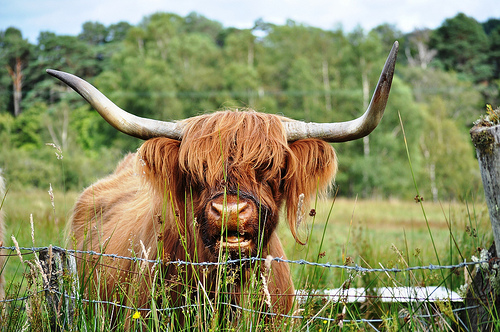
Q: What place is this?
A: It is a field.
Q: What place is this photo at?
A: It is at the field.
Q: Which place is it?
A: It is a field.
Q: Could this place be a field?
A: Yes, it is a field.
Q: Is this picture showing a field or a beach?
A: It is showing a field.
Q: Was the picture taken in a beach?
A: No, the picture was taken in a field.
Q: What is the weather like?
A: It is cloudy.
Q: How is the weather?
A: It is cloudy.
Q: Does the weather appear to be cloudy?
A: Yes, it is cloudy.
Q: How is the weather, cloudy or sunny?
A: It is cloudy.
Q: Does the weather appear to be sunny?
A: No, it is cloudy.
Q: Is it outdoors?
A: Yes, it is outdoors.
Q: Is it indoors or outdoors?
A: It is outdoors.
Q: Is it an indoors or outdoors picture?
A: It is outdoors.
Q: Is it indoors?
A: No, it is outdoors.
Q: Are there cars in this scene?
A: No, there are no cars.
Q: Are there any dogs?
A: No, there are no dogs.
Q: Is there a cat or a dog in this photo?
A: No, there are no dogs or cats.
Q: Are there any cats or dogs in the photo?
A: No, there are no dogs or cats.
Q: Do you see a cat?
A: No, there are no cats.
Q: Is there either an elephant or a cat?
A: No, there are no cats or elephants.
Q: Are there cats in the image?
A: No, there are no cats.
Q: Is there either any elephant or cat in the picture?
A: No, there are no cats or elephants.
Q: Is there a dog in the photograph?
A: No, there are no dogs.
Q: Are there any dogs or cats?
A: No, there are no dogs or cats.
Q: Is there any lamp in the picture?
A: No, there are no lamps.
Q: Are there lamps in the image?
A: No, there are no lamps.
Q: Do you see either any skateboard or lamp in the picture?
A: No, there are no lamps or skateboards.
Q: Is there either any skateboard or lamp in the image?
A: No, there are no lamps or skateboards.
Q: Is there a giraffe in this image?
A: No, there are no giraffes.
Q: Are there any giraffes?
A: No, there are no giraffes.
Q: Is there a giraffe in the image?
A: No, there are no giraffes.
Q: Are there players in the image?
A: No, there are no players.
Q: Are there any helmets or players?
A: No, there are no players or helmets.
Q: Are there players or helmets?
A: No, there are no players or helmets.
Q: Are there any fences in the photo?
A: Yes, there is a fence.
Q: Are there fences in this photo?
A: Yes, there is a fence.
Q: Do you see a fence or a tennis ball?
A: Yes, there is a fence.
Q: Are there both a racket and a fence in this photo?
A: No, there is a fence but no rackets.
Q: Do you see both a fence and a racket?
A: No, there is a fence but no rackets.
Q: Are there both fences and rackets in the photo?
A: No, there is a fence but no rackets.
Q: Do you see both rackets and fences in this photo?
A: No, there is a fence but no rackets.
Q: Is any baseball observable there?
A: No, there are no baseballs.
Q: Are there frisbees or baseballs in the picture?
A: No, there are no baseballs or frisbees.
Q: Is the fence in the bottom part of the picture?
A: Yes, the fence is in the bottom of the image.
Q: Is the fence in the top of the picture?
A: No, the fence is in the bottom of the image.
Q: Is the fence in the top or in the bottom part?
A: The fence is in the bottom of the image.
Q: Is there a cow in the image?
A: Yes, there is a cow.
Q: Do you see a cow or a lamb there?
A: Yes, there is a cow.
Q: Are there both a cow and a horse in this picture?
A: No, there is a cow but no horses.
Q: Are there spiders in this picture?
A: No, there are no spiders.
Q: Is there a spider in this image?
A: No, there are no spiders.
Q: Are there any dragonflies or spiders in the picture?
A: No, there are no spiders or dragonflies.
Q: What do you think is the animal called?
A: The animal is a cow.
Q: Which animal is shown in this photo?
A: The animal is a cow.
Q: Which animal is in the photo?
A: The animal is a cow.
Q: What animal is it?
A: The animal is a cow.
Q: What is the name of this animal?
A: That is a cow.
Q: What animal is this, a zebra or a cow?
A: That is a cow.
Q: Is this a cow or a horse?
A: This is a cow.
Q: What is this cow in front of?
A: The cow is in front of the trees.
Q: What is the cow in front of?
A: The cow is in front of the trees.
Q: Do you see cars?
A: No, there are no cars.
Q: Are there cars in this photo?
A: No, there are no cars.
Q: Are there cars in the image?
A: No, there are no cars.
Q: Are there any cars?
A: No, there are no cars.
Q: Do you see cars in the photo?
A: No, there are no cars.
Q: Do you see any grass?
A: Yes, there is grass.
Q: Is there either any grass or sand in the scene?
A: Yes, there is grass.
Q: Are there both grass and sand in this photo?
A: No, there is grass but no sand.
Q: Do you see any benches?
A: No, there are no benches.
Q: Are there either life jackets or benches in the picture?
A: No, there are no benches or life jackets.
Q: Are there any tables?
A: Yes, there is a table.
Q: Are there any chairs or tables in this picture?
A: Yes, there is a table.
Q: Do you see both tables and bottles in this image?
A: No, there is a table but no bottles.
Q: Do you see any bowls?
A: No, there are no bowls.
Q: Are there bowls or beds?
A: No, there are no bowls or beds.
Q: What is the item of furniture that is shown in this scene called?
A: The piece of furniture is a table.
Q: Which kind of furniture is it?
A: The piece of furniture is a table.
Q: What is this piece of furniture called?
A: This is a table.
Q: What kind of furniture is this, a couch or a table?
A: This is a table.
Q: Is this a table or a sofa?
A: This is a table.